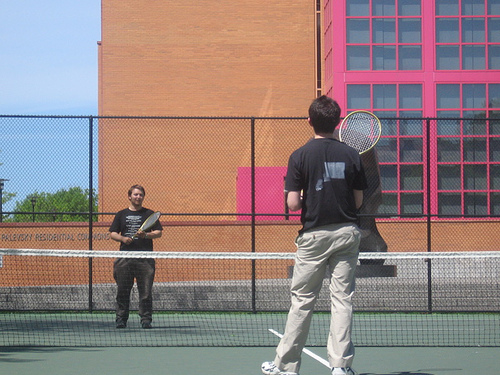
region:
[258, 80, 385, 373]
man facing the other way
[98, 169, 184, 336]
man facing the camera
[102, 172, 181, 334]
man holding a tennis racquet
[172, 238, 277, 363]
a tennis net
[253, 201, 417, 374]
white long pants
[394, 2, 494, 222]
pink painted window frames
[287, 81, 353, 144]
a dark haired man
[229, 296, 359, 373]
white line on a tennis court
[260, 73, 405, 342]
man with his back facing the camera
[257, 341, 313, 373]
white tennis shoe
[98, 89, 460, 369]
two men on a tennis court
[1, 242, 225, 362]
a tennis court net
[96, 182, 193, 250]
man holding a tennis racket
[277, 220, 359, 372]
man wearing gray pants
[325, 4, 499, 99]
a building painted pink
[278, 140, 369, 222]
man wearing a black T-shirt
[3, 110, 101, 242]
a black metal fence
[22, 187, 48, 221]
a streetlamp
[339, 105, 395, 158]
a silver tennis racket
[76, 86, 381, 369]
two tennis players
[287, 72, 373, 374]
Boy playing tennis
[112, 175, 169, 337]
Holding racket with both hands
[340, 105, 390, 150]
Racket is white and yellow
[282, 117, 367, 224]
Shirt is black and short sleeves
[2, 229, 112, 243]
Letters on building in background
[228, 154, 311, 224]
Red box on building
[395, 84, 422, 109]
Window is clear and clean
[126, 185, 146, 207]
Face is white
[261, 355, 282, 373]
Left shoe is laced and white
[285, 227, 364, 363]
Pants are tan and long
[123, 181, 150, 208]
the head of a man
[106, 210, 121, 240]
the arm of a man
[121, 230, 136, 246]
the hand of a man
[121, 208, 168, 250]
a tennis racket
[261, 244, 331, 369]
the leg of a man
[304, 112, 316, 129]
the ear of a man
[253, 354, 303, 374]
a white tennis shoe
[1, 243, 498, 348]
a white and black net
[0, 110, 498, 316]
a large chain link fence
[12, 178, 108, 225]
a green tree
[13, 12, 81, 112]
The sky is blue.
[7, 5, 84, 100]
The sky is clear.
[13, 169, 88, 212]
Trees are in the background.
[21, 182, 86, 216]
The trees are green.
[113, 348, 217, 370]
The ground is green.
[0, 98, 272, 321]
A fence is in the background.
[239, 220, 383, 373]
The person is wearing white pants.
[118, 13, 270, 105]
The building is red.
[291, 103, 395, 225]
The person is holding a tennis racket.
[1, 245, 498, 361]
A tennis net.